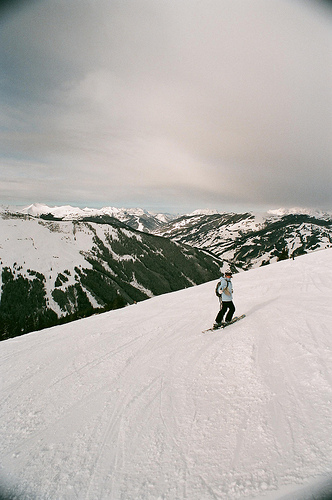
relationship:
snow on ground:
[0, 205, 332, 500] [1, 244, 330, 499]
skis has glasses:
[202, 314, 246, 333] [225, 272, 231, 275]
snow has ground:
[0, 205, 332, 500] [0, 351, 331, 496]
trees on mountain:
[0, 278, 51, 337] [1, 206, 234, 343]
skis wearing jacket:
[202, 314, 246, 333] [207, 277, 242, 311]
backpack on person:
[213, 277, 222, 303] [212, 269, 238, 329]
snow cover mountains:
[0, 205, 332, 500] [11, 200, 327, 288]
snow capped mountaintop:
[0, 205, 332, 500] [11, 194, 90, 217]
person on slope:
[208, 263, 237, 333] [4, 241, 331, 498]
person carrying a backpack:
[213, 267, 235, 326] [213, 278, 224, 297]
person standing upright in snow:
[213, 267, 235, 326] [129, 283, 310, 435]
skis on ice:
[202, 313, 245, 333] [0, 245, 330, 498]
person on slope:
[213, 267, 235, 326] [4, 241, 331, 498]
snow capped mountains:
[54, 203, 80, 213] [0, 206, 330, 341]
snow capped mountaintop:
[0, 205, 332, 500] [103, 203, 122, 217]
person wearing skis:
[213, 267, 235, 326] [203, 314, 245, 331]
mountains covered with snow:
[0, 206, 330, 341] [175, 395, 235, 440]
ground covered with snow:
[117, 218, 184, 273] [280, 249, 313, 282]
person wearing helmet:
[213, 267, 235, 326] [221, 265, 232, 275]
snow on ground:
[0, 205, 332, 500] [76, 424, 160, 473]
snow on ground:
[6, 205, 326, 495] [217, 405, 259, 469]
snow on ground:
[0, 205, 332, 500] [96, 386, 147, 478]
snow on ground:
[0, 205, 332, 500] [52, 325, 331, 497]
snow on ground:
[0, 205, 332, 500] [229, 387, 304, 465]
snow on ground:
[0, 205, 332, 500] [203, 414, 317, 488]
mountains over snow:
[0, 206, 330, 341] [161, 394, 227, 457]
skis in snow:
[202, 314, 246, 333] [247, 390, 303, 463]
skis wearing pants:
[202, 314, 246, 333] [218, 300, 232, 325]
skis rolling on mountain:
[202, 314, 246, 333] [1, 244, 329, 498]